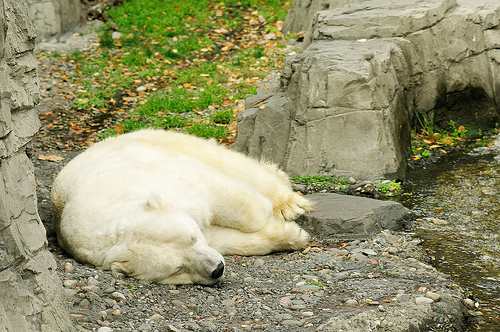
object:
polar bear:
[53, 128, 312, 285]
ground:
[0, 3, 499, 332]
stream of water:
[405, 140, 499, 332]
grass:
[45, 0, 301, 139]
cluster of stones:
[0, 0, 69, 331]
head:
[111, 193, 225, 289]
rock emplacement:
[230, 6, 500, 176]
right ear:
[107, 256, 134, 277]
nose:
[209, 260, 224, 279]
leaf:
[117, 49, 131, 65]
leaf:
[142, 56, 158, 65]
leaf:
[249, 17, 260, 28]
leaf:
[170, 34, 183, 44]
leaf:
[169, 47, 180, 57]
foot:
[284, 196, 314, 221]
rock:
[290, 190, 413, 248]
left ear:
[145, 193, 165, 211]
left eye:
[185, 233, 199, 244]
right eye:
[173, 264, 187, 275]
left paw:
[244, 195, 271, 232]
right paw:
[268, 220, 309, 251]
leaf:
[221, 40, 235, 56]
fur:
[55, 125, 307, 285]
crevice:
[393, 88, 499, 182]